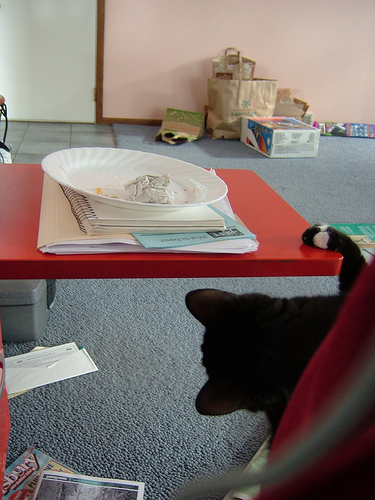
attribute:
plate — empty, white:
[42, 140, 236, 219]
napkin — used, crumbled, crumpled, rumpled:
[111, 166, 180, 208]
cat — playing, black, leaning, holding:
[171, 221, 359, 420]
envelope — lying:
[2, 336, 107, 399]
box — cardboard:
[238, 109, 323, 166]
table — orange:
[2, 160, 345, 282]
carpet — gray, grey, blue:
[279, 137, 373, 227]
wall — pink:
[104, 2, 374, 135]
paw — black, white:
[303, 219, 340, 253]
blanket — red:
[262, 239, 375, 500]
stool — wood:
[1, 94, 19, 167]